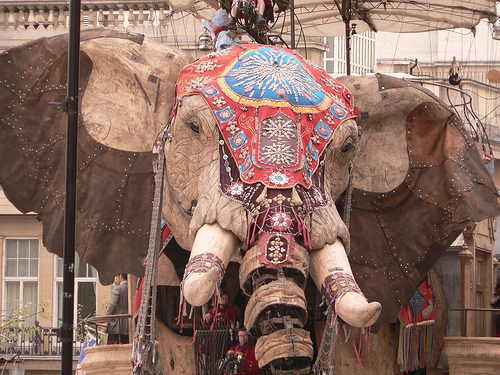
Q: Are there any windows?
A: Yes, there is a window.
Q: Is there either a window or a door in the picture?
A: Yes, there is a window.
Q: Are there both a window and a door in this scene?
A: No, there is a window but no doors.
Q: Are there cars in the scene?
A: No, there are no cars.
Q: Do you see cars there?
A: No, there are no cars.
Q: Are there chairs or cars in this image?
A: No, there are no cars or chairs.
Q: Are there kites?
A: No, there are no kites.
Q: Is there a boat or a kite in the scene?
A: No, there are no kites or boats.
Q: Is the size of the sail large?
A: Yes, the sail is large.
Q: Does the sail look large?
A: Yes, the sail is large.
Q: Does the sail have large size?
A: Yes, the sail is large.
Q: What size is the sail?
A: The sail is large.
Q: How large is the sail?
A: The sail is large.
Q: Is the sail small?
A: No, the sail is large.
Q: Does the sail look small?
A: No, the sail is large.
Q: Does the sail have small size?
A: No, the sail is large.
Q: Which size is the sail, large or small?
A: The sail is large.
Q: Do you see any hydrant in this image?
A: No, there are no fire hydrants.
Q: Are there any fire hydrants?
A: No, there are no fire hydrants.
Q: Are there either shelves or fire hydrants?
A: No, there are no fire hydrants or shelves.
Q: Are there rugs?
A: No, there are no rugs.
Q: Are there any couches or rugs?
A: No, there are no rugs or couches.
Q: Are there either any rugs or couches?
A: No, there are no rugs or couches.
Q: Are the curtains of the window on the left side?
A: Yes, the curtains are on the left of the image.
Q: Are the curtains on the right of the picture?
A: No, the curtains are on the left of the image.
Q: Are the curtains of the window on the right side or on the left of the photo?
A: The curtains are on the left of the image.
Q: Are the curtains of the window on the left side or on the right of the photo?
A: The curtains are on the left of the image.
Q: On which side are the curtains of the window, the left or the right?
A: The curtains are on the left of the image.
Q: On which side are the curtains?
A: The curtains are on the left of the image.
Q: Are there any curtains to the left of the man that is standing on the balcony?
A: Yes, there are curtains to the left of the man.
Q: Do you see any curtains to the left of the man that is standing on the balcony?
A: Yes, there are curtains to the left of the man.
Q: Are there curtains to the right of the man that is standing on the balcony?
A: No, the curtains are to the left of the man.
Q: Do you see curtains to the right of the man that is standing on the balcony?
A: No, the curtains are to the left of the man.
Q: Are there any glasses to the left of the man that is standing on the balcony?
A: No, there are curtains to the left of the man.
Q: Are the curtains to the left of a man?
A: Yes, the curtains are to the left of a man.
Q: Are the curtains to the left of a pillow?
A: No, the curtains are to the left of a man.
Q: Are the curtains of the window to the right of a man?
A: No, the curtains are to the left of a man.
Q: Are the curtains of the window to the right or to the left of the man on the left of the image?
A: The curtains are to the left of the man.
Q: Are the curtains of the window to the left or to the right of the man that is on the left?
A: The curtains are to the left of the man.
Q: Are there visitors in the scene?
A: No, there are no visitors.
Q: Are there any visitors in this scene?
A: No, there are no visitors.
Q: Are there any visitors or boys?
A: No, there are no visitors or boys.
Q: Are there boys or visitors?
A: No, there are no visitors or boys.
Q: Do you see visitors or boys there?
A: No, there are no visitors or boys.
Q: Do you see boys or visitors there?
A: No, there are no visitors or boys.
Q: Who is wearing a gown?
A: The man is wearing a gown.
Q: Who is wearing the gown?
A: The man is wearing a gown.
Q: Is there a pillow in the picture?
A: No, there are no pillows.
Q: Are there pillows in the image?
A: No, there are no pillows.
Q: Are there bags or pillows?
A: No, there are no pillows or bags.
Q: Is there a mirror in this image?
A: No, there are no mirrors.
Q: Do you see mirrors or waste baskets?
A: No, there are no mirrors or waste baskets.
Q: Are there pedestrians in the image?
A: No, there are no pedestrians.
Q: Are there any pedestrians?
A: No, there are no pedestrians.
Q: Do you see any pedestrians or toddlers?
A: No, there are no pedestrians or toddlers.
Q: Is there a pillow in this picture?
A: No, there are no pillows.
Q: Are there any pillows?
A: No, there are no pillows.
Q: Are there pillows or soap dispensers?
A: No, there are no pillows or soap dispensers.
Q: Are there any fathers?
A: No, there are no fathers.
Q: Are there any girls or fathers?
A: No, there are no fathers or girls.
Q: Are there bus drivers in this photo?
A: No, there are no bus drivers.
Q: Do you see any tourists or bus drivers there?
A: No, there are no bus drivers or tourists.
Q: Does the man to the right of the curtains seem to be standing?
A: Yes, the man is standing.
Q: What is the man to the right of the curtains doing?
A: The man is standing.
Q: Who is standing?
A: The man is standing.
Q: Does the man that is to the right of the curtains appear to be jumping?
A: No, the man is standing.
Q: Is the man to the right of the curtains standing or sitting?
A: The man is standing.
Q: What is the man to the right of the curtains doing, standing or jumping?
A: The man is standing.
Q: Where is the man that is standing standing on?
A: The man is standing on the balcony.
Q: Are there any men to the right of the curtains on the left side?
A: Yes, there is a man to the right of the curtains.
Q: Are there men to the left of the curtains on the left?
A: No, the man is to the right of the curtains.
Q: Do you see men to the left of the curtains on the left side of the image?
A: No, the man is to the right of the curtains.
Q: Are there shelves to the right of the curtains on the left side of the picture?
A: No, there is a man to the right of the curtains.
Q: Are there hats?
A: Yes, there is a hat.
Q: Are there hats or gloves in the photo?
A: Yes, there is a hat.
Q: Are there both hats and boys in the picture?
A: No, there is a hat but no boys.